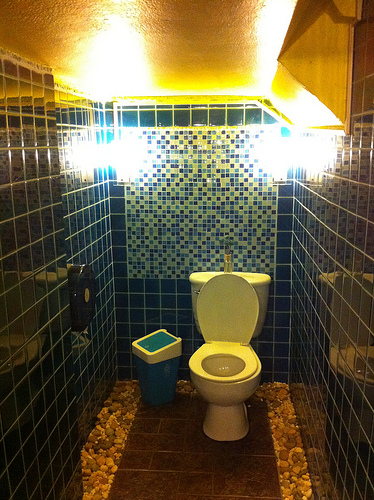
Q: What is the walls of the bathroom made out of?
A: Tile.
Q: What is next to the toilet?
A: Garbage can.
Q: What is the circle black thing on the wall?
A: Toilet paper holder.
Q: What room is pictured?
A: A bathroom.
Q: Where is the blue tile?
A: On the bathroom walls.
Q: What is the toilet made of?
A: Porcelain.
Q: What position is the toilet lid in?
A: Open.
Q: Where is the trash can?
A: Next to the toilet.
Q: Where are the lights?
A: On the ceiling.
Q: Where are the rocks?
A: Around the perimeter of the floor.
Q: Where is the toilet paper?
A: On the wall.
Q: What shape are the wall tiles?
A: Squares.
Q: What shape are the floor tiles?
A: Square.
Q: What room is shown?
A: Bathroom.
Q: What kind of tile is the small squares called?
A: Mosaic.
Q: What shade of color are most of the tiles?
A: Blue.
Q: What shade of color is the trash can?
A: Blue and white.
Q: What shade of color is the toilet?
A: White.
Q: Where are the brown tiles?
A: On the floor.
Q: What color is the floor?
A: Brown.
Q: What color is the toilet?
A: White.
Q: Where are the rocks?
A: The floor.